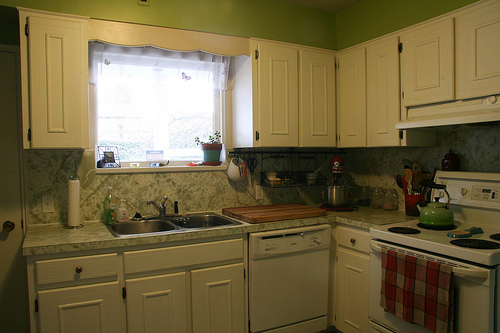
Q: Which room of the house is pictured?
A: It is a kitchen.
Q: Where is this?
A: This is at the kitchen.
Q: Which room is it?
A: It is a kitchen.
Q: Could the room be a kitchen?
A: Yes, it is a kitchen.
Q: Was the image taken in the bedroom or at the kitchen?
A: It was taken at the kitchen.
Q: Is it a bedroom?
A: No, it is a kitchen.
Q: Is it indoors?
A: Yes, it is indoors.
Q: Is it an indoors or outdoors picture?
A: It is indoors.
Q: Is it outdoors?
A: No, it is indoors.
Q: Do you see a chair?
A: No, there are no chairs.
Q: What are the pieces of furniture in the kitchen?
A: The pieces of furniture are cabinets.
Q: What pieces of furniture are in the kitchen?
A: The pieces of furniture are cabinets.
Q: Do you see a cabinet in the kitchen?
A: Yes, there are cabinets in the kitchen.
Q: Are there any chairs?
A: No, there are no chairs.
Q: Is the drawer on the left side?
A: Yes, the drawer is on the left of the image.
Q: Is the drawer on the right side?
A: No, the drawer is on the left of the image.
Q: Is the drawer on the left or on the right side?
A: The drawer is on the left of the image.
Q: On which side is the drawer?
A: The drawer is on the left of the image.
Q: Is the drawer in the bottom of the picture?
A: Yes, the drawer is in the bottom of the image.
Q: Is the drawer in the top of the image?
A: No, the drawer is in the bottom of the image.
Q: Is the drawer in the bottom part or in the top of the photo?
A: The drawer is in the bottom of the image.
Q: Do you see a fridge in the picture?
A: No, there are no refrigerators.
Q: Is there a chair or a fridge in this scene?
A: No, there are no refrigerators or chairs.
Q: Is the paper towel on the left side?
A: Yes, the paper towel is on the left of the image.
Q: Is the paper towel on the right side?
A: No, the paper towel is on the left of the image.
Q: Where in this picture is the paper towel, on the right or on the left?
A: The paper towel is on the left of the image.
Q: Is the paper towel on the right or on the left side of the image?
A: The paper towel is on the left of the image.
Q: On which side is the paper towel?
A: The paper towel is on the left of the image.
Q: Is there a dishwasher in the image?
A: Yes, there is a dishwasher.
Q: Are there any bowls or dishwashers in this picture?
A: Yes, there is a dishwasher.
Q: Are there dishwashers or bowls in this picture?
A: Yes, there is a dishwasher.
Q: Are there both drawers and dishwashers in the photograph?
A: Yes, there are both a dishwasher and a drawer.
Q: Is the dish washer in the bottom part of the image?
A: Yes, the dish washer is in the bottom of the image.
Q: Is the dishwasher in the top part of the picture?
A: No, the dishwasher is in the bottom of the image.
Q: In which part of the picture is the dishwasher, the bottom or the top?
A: The dishwasher is in the bottom of the image.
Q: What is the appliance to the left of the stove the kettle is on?
A: The appliance is a dishwasher.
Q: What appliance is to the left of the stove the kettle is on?
A: The appliance is a dishwasher.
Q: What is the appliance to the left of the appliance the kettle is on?
A: The appliance is a dishwasher.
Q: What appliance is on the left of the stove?
A: The appliance is a dishwasher.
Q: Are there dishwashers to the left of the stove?
A: Yes, there is a dishwasher to the left of the stove.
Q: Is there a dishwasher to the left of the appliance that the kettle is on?
A: Yes, there is a dishwasher to the left of the stove.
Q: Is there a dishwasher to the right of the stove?
A: No, the dishwasher is to the left of the stove.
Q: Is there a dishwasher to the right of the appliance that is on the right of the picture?
A: No, the dishwasher is to the left of the stove.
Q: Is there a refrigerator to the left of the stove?
A: No, there is a dishwasher to the left of the stove.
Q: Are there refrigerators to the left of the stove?
A: No, there is a dishwasher to the left of the stove.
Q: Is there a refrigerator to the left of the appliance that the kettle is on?
A: No, there is a dishwasher to the left of the stove.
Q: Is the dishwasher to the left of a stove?
A: Yes, the dishwasher is to the left of a stove.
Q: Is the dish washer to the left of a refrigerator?
A: No, the dish washer is to the left of a stove.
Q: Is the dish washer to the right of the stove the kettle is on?
A: No, the dish washer is to the left of the stove.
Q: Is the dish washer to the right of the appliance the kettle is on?
A: No, the dish washer is to the left of the stove.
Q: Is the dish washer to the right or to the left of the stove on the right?
A: The dish washer is to the left of the stove.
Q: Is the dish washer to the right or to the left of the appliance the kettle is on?
A: The dish washer is to the left of the stove.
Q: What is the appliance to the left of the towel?
A: The appliance is a dishwasher.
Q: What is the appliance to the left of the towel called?
A: The appliance is a dishwasher.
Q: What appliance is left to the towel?
A: The appliance is a dishwasher.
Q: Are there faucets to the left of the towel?
A: No, there is a dishwasher to the left of the towel.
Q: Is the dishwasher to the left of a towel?
A: Yes, the dishwasher is to the left of a towel.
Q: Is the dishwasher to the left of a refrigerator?
A: No, the dishwasher is to the left of a towel.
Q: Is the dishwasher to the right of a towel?
A: No, the dishwasher is to the left of a towel.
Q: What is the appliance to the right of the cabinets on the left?
A: The appliance is a dishwasher.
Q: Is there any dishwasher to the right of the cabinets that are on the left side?
A: Yes, there is a dishwasher to the right of the cabinets.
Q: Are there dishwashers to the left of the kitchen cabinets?
A: No, the dishwasher is to the right of the cabinets.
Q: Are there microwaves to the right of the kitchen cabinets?
A: No, there is a dishwasher to the right of the cabinets.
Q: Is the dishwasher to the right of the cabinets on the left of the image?
A: Yes, the dishwasher is to the right of the cabinets.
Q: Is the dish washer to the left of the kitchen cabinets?
A: No, the dish washer is to the right of the cabinets.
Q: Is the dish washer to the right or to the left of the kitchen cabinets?
A: The dish washer is to the right of the cabinets.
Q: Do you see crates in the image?
A: No, there are no crates.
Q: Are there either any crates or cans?
A: No, there are no crates or cans.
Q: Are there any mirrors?
A: No, there are no mirrors.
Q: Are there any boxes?
A: No, there are no boxes.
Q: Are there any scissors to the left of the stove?
A: Yes, there are scissors to the left of the stove.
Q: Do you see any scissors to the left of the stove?
A: Yes, there are scissors to the left of the stove.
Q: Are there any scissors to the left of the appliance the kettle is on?
A: Yes, there are scissors to the left of the stove.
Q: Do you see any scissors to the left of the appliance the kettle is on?
A: Yes, there are scissors to the left of the stove.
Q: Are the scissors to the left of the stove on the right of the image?
A: Yes, the scissors are to the left of the stove.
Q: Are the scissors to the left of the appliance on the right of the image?
A: Yes, the scissors are to the left of the stove.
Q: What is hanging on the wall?
A: The scissors are hanging on the wall.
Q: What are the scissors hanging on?
A: The scissors are hanging on the wall.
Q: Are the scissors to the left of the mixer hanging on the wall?
A: Yes, the scissors are hanging on the wall.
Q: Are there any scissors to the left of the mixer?
A: Yes, there are scissors to the left of the mixer.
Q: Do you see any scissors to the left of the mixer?
A: Yes, there are scissors to the left of the mixer.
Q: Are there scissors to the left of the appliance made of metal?
A: Yes, there are scissors to the left of the mixer.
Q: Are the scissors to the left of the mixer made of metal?
A: Yes, the scissors are to the left of the mixer.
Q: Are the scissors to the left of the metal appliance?
A: Yes, the scissors are to the left of the mixer.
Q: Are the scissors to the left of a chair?
A: No, the scissors are to the left of the mixer.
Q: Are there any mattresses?
A: No, there are no mattresses.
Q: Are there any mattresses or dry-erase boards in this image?
A: No, there are no mattresses or dry-erase boards.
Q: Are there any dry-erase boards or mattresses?
A: No, there are no mattresses or dry-erase boards.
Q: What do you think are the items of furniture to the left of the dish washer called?
A: The pieces of furniture are cabinets.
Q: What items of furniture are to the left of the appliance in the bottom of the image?
A: The pieces of furniture are cabinets.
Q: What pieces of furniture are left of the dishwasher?
A: The pieces of furniture are cabinets.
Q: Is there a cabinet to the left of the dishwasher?
A: Yes, there are cabinets to the left of the dishwasher.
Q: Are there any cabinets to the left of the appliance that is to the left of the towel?
A: Yes, there are cabinets to the left of the dishwasher.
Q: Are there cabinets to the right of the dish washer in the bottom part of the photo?
A: No, the cabinets are to the left of the dishwasher.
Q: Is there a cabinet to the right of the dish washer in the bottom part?
A: No, the cabinets are to the left of the dishwasher.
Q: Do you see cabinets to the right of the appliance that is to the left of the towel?
A: No, the cabinets are to the left of the dishwasher.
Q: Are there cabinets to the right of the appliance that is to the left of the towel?
A: No, the cabinets are to the left of the dishwasher.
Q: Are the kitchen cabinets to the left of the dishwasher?
A: Yes, the cabinets are to the left of the dishwasher.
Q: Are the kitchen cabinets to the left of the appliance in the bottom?
A: Yes, the cabinets are to the left of the dishwasher.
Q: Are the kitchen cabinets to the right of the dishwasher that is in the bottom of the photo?
A: No, the cabinets are to the left of the dishwasher.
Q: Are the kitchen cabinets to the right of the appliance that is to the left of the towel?
A: No, the cabinets are to the left of the dishwasher.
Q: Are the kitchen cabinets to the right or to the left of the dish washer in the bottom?
A: The cabinets are to the left of the dishwasher.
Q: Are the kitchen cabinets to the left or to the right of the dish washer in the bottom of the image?
A: The cabinets are to the left of the dishwasher.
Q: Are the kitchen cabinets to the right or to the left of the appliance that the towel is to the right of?
A: The cabinets are to the left of the dishwasher.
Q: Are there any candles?
A: No, there are no candles.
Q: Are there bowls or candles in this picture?
A: No, there are no candles or bowls.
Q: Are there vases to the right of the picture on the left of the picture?
A: Yes, there is a vase to the right of the picture.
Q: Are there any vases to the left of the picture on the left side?
A: No, the vase is to the right of the picture.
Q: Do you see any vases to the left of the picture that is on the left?
A: No, the vase is to the right of the picture.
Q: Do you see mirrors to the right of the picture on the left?
A: No, there is a vase to the right of the picture.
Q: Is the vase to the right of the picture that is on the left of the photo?
A: Yes, the vase is to the right of the picture.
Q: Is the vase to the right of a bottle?
A: No, the vase is to the right of the picture.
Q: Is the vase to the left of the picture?
A: No, the vase is to the right of the picture.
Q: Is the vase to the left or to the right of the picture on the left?
A: The vase is to the right of the picture.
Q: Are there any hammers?
A: No, there are no hammers.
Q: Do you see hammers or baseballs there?
A: No, there are no hammers or baseballs.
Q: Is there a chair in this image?
A: No, there are no chairs.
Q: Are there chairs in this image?
A: No, there are no chairs.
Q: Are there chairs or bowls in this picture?
A: No, there are no chairs or bowls.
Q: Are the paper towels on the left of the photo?
A: Yes, the paper towels are on the left of the image.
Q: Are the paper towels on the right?
A: No, the paper towels are on the left of the image.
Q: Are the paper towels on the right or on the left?
A: The paper towels are on the left of the image.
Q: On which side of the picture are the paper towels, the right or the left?
A: The paper towels are on the left of the image.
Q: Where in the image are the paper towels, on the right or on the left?
A: The paper towels are on the left of the image.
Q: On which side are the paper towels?
A: The paper towels are on the left of the image.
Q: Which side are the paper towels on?
A: The paper towels are on the left of the image.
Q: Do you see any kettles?
A: Yes, there is a kettle.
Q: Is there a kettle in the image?
A: Yes, there is a kettle.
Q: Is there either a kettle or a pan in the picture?
A: Yes, there is a kettle.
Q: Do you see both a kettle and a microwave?
A: No, there is a kettle but no microwaves.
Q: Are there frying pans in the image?
A: No, there are no frying pans.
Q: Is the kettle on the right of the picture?
A: Yes, the kettle is on the right of the image.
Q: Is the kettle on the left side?
A: No, the kettle is on the right of the image.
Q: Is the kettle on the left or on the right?
A: The kettle is on the right of the image.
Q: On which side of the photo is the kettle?
A: The kettle is on the right of the image.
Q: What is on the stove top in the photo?
A: The kettle is on the stove top.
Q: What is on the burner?
A: The kettle is on the stove top.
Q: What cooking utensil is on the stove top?
A: The cooking utensil is a kettle.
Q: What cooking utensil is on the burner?
A: The cooking utensil is a kettle.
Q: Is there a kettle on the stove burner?
A: Yes, there is a kettle on the stove burner.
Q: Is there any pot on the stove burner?
A: No, there is a kettle on the stove burner.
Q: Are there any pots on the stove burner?
A: No, there is a kettle on the stove burner.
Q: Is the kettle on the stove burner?
A: Yes, the kettle is on the stove burner.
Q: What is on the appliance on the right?
A: The kettle is on the stove.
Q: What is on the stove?
A: The kettle is on the stove.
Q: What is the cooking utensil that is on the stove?
A: The cooking utensil is a kettle.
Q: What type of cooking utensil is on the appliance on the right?
A: The cooking utensil is a kettle.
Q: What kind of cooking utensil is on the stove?
A: The cooking utensil is a kettle.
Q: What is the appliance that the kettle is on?
A: The appliance is a stove.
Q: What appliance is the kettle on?
A: The kettle is on the stove.